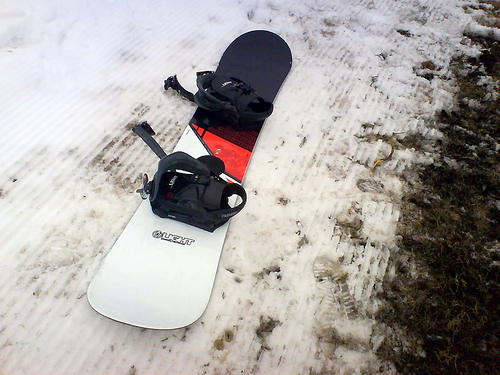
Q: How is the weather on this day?
A: It is sunny.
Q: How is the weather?
A: It is sunny.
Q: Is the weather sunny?
A: Yes, it is sunny.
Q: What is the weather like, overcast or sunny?
A: It is sunny.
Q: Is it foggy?
A: No, it is sunny.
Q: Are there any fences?
A: No, there are no fences.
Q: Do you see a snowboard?
A: Yes, there is a snowboard.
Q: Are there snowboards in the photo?
A: Yes, there is a snowboard.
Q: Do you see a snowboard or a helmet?
A: Yes, there is a snowboard.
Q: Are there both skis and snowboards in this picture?
A: No, there is a snowboard but no skis.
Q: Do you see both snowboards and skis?
A: No, there is a snowboard but no skis.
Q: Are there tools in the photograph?
A: No, there are no tools.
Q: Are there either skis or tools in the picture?
A: No, there are no tools or skis.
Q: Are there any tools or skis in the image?
A: No, there are no tools or skis.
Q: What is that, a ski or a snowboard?
A: That is a snowboard.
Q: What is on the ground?
A: The snowboard is on the ground.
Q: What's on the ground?
A: The snowboard is on the ground.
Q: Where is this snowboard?
A: The snowboard is on the ground.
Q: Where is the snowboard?
A: The snowboard is on the ground.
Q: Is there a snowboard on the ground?
A: Yes, there is a snowboard on the ground.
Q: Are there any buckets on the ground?
A: No, there is a snowboard on the ground.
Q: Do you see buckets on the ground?
A: No, there is a snowboard on the ground.